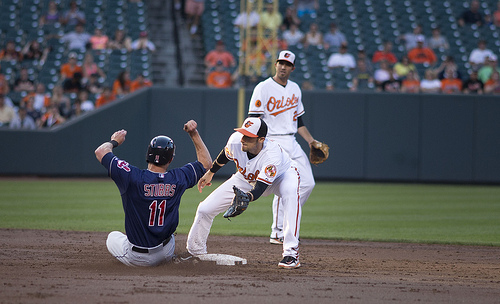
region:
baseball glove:
[223, 181, 259, 226]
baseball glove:
[230, 181, 281, 239]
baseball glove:
[213, 168, 262, 236]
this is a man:
[107, 136, 198, 278]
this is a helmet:
[144, 135, 176, 157]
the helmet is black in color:
[154, 137, 169, 155]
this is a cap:
[243, 112, 261, 132]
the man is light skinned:
[192, 137, 207, 151]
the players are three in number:
[113, 65, 323, 260]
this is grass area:
[368, 184, 464, 221]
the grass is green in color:
[348, 190, 410, 214]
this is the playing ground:
[245, 270, 425, 291]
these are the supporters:
[352, 25, 492, 84]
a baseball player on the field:
[93, 121, 210, 262]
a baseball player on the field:
[190, 116, 301, 270]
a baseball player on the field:
[250, 48, 330, 249]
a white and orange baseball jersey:
[247, 80, 304, 137]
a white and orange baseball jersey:
[226, 130, 288, 184]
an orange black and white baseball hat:
[235, 116, 266, 137]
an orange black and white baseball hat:
[276, 50, 293, 64]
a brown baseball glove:
[309, 138, 329, 158]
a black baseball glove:
[224, 186, 251, 213]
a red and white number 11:
[147, 196, 169, 228]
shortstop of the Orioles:
[253, 37, 332, 99]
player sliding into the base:
[99, 109, 222, 245]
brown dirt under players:
[350, 239, 413, 298]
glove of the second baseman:
[215, 182, 260, 239]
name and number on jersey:
[133, 173, 190, 233]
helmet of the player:
[139, 125, 186, 178]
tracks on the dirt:
[379, 228, 449, 296]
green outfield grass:
[376, 173, 447, 229]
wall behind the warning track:
[382, 92, 464, 173]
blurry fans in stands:
[366, 8, 472, 90]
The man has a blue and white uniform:
[82, 121, 234, 270]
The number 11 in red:
[129, 168, 196, 258]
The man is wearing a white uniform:
[241, 44, 336, 276]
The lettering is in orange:
[246, 85, 303, 127]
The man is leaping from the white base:
[173, 122, 293, 268]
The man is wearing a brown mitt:
[223, 168, 270, 238]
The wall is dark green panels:
[11, 74, 468, 191]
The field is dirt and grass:
[30, 151, 442, 290]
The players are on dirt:
[67, 33, 334, 280]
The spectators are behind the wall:
[19, 22, 471, 112]